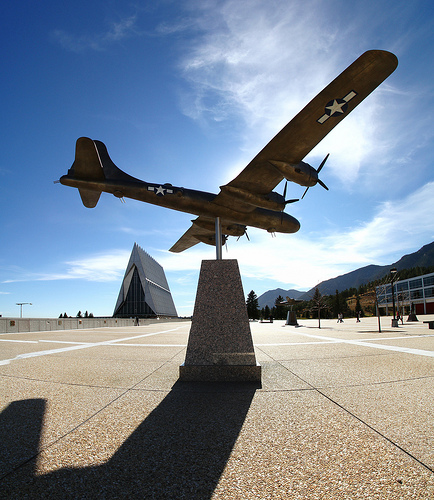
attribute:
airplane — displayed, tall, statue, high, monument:
[60, 46, 402, 256]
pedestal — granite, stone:
[175, 259, 263, 385]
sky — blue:
[3, 3, 433, 306]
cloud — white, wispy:
[233, 235, 329, 286]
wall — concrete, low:
[3, 313, 188, 336]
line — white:
[330, 334, 431, 371]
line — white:
[5, 335, 103, 380]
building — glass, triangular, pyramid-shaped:
[111, 241, 183, 323]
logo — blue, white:
[143, 182, 178, 200]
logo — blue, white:
[314, 82, 363, 130]